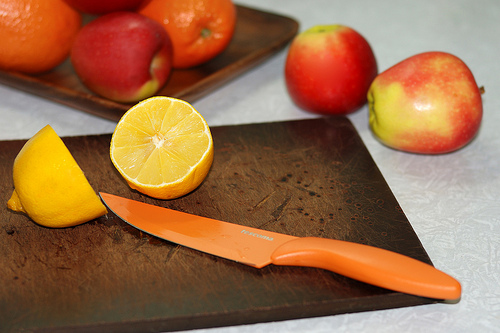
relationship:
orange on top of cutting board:
[139, 1, 236, 69] [2, 2, 297, 115]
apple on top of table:
[285, 25, 377, 116] [2, 2, 498, 331]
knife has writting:
[98, 193, 462, 300] [239, 229, 272, 242]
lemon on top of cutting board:
[109, 95, 214, 198] [3, 117, 443, 331]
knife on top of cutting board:
[98, 193, 462, 300] [3, 117, 443, 331]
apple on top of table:
[368, 52, 486, 155] [2, 2, 498, 331]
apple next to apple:
[285, 25, 377, 116] [368, 52, 486, 155]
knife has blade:
[98, 193, 462, 300] [100, 192, 299, 269]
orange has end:
[139, 1, 236, 69] [201, 26, 212, 39]